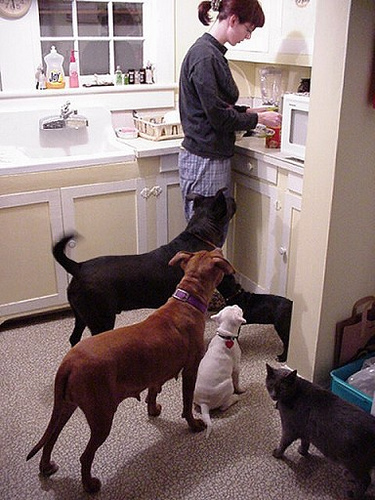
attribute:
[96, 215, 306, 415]
dogs — white, brown, close, waiting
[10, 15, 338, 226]
kitchen — crowded, white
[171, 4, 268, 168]
woman — standing, close, thin, white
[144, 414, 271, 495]
floor — below, fluffy, grey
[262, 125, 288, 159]
can — close, red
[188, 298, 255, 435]
pet — is exicted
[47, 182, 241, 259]
pet — is exicted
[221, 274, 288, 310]
pet — is exicted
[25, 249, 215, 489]
pet — is exicted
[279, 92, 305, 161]
moicrowave — is white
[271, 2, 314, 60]
cupboard — is white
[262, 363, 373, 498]
cat — is black